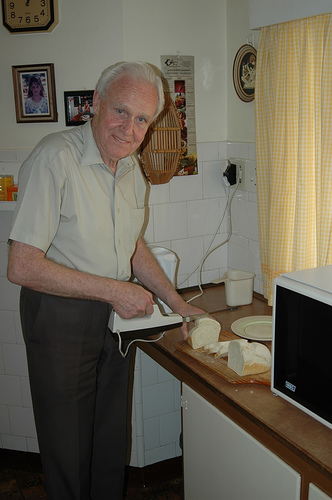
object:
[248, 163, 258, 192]
outlet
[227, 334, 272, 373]
bread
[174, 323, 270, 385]
cutting board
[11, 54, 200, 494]
man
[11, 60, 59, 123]
picture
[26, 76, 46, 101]
girl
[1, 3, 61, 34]
clock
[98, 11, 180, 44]
wall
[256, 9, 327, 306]
curtain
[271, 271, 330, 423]
microwave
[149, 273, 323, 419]
counter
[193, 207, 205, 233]
white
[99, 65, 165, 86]
white hair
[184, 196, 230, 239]
tiles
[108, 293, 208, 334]
carving knife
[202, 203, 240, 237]
cords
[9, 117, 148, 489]
dressed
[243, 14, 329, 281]
window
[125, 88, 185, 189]
wooden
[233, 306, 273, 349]
white plate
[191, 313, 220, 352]
sliced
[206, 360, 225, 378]
wood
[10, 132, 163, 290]
shirt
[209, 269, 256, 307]
cup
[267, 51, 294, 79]
yellow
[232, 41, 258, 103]
plate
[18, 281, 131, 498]
brown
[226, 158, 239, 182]
electrical outlet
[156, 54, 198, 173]
poster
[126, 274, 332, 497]
table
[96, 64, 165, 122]
gray hair